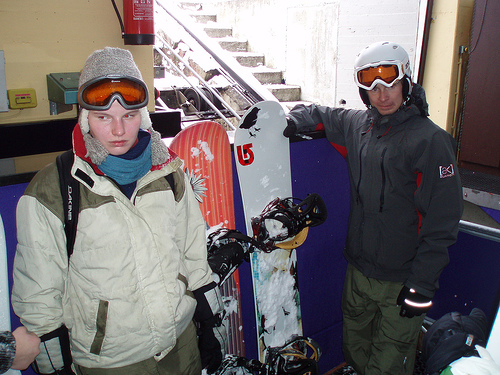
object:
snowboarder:
[11, 43, 225, 374]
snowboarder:
[284, 41, 467, 374]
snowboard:
[232, 98, 317, 375]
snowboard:
[158, 120, 256, 373]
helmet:
[350, 44, 416, 114]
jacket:
[286, 98, 480, 301]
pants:
[341, 256, 428, 374]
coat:
[8, 119, 219, 367]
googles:
[76, 74, 148, 110]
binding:
[247, 190, 329, 252]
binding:
[265, 333, 322, 374]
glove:
[199, 322, 225, 374]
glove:
[392, 289, 432, 320]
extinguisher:
[118, 1, 156, 44]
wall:
[1, 0, 164, 117]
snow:
[264, 81, 298, 89]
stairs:
[265, 81, 301, 103]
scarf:
[87, 132, 164, 187]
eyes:
[91, 110, 111, 119]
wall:
[0, 109, 392, 371]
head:
[76, 44, 145, 159]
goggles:
[352, 64, 397, 90]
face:
[88, 98, 142, 156]